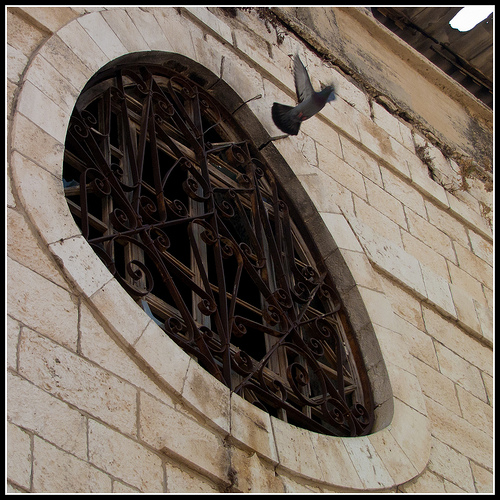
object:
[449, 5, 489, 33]
hole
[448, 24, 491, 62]
rood tile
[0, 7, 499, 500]
house wall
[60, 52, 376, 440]
window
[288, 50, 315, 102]
wing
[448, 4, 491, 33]
sky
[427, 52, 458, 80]
tiles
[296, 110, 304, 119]
leg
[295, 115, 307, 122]
leg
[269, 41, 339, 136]
bird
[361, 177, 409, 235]
brick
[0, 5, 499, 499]
brick house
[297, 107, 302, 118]
legs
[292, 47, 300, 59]
tip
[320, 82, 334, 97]
head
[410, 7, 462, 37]
tile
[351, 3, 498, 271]
air